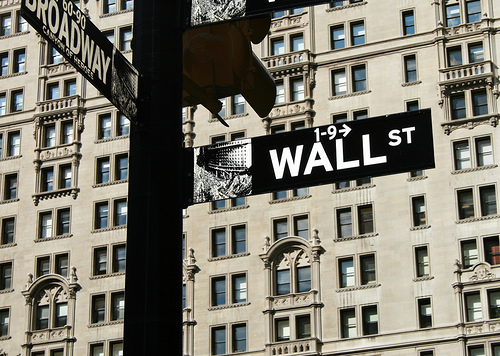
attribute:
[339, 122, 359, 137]
arrow — small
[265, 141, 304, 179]
letter — white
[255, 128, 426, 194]
sign — white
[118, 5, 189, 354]
pole — black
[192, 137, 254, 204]
logo — black, white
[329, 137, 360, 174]
letter — white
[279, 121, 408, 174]
letter — white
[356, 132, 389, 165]
letter — white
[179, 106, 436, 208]
sign — black, white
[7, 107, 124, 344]
building — large, gray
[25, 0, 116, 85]
lettering — white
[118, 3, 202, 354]
pole — black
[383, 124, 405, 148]
letter — white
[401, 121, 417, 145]
letter — white